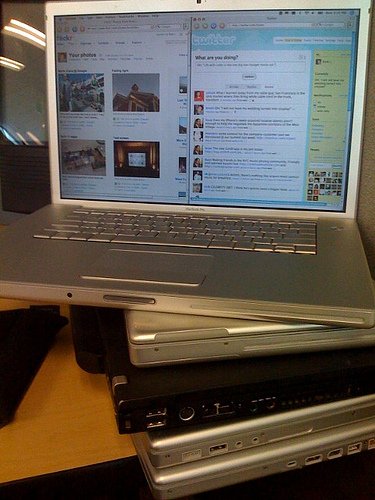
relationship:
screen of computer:
[58, 15, 351, 201] [0, 0, 375, 326]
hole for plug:
[176, 405, 196, 419] [203, 437, 230, 456]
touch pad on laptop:
[75, 241, 216, 291] [20, 3, 363, 259]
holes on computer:
[236, 421, 273, 445] [31, 12, 362, 317]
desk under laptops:
[0, 296, 138, 482] [1, 5, 362, 328]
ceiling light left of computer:
[3, 16, 46, 54] [0, 0, 375, 326]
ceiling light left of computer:
[0, 54, 26, 75] [0, 0, 375, 326]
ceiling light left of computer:
[22, 127, 46, 149] [0, 0, 375, 326]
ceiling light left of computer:
[13, 128, 28, 146] [0, 0, 375, 326]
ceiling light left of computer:
[1, 124, 19, 146] [0, 0, 375, 326]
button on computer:
[328, 223, 343, 231] [0, 0, 375, 326]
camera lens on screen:
[195, 0, 201, 5] [46, 4, 363, 207]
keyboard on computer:
[36, 203, 335, 273] [0, 0, 375, 326]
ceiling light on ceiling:
[4, 19, 47, 51] [0, 4, 44, 87]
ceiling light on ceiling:
[0, 54, 26, 72] [0, 4, 44, 87]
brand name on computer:
[182, 202, 209, 215] [0, 0, 375, 326]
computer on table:
[0, 0, 375, 326] [0, 297, 374, 498]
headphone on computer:
[251, 432, 259, 446] [0, 0, 375, 326]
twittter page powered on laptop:
[186, 12, 353, 213] [40, 10, 363, 243]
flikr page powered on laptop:
[50, 6, 193, 207] [25, 31, 336, 266]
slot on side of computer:
[302, 452, 324, 465] [0, 0, 375, 326]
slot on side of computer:
[325, 444, 346, 461] [0, 0, 375, 326]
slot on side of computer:
[347, 439, 361, 454] [0, 0, 375, 326]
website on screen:
[54, 7, 363, 214] [46, 4, 363, 207]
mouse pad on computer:
[76, 237, 221, 298] [0, 0, 375, 326]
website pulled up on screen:
[40, 11, 354, 206] [46, 4, 363, 207]